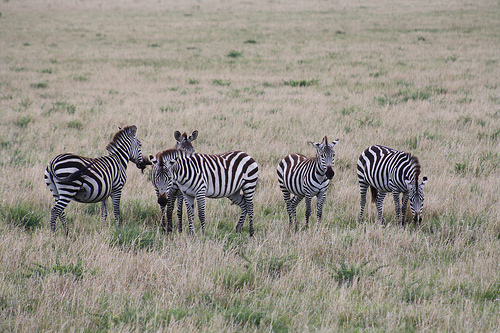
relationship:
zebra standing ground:
[361, 142, 433, 227] [0, 0, 500, 333]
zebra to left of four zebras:
[24, 129, 147, 231] [146, 121, 431, 228]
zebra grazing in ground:
[355, 143, 429, 230] [0, 0, 500, 333]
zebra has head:
[276, 136, 337, 227] [304, 131, 344, 184]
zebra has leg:
[355, 143, 429, 230] [156, 202, 192, 238]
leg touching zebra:
[156, 202, 192, 238] [355, 143, 429, 230]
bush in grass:
[327, 256, 367, 287] [336, 262, 370, 289]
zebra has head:
[271, 136, 361, 216] [308, 133, 352, 174]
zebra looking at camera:
[275, 135, 344, 234] [264, 110, 386, 286]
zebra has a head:
[145, 149, 260, 238] [146, 150, 180, 208]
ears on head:
[171, 132, 215, 143] [163, 117, 203, 150]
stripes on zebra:
[171, 145, 258, 199] [152, 147, 269, 218]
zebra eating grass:
[355, 143, 429, 230] [0, 1, 499, 331]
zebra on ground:
[355, 143, 429, 230] [0, 0, 500, 333]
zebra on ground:
[275, 135, 344, 234] [0, 0, 500, 333]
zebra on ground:
[151, 147, 271, 234] [0, 0, 500, 333]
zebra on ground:
[41, 124, 148, 239] [0, 0, 500, 333]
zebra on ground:
[167, 128, 203, 155] [0, 0, 500, 333]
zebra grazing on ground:
[355, 143, 429, 230] [0, 0, 500, 333]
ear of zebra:
[420, 176, 427, 190] [355, 143, 429, 230]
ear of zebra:
[403, 174, 410, 189] [355, 143, 429, 230]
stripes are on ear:
[166, 154, 178, 167] [168, 154, 178, 166]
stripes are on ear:
[148, 155, 157, 168] [149, 152, 157, 169]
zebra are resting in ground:
[41, 124, 148, 239] [0, 0, 500, 333]